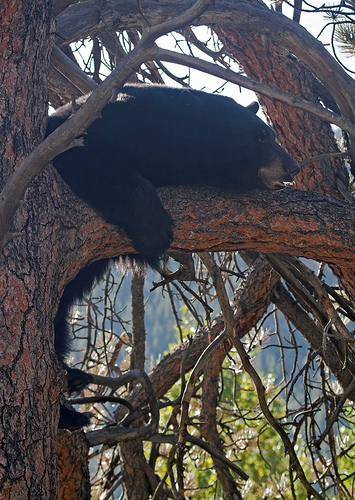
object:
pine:
[0, 0, 355, 500]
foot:
[64, 368, 93, 391]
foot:
[58, 404, 89, 432]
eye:
[258, 133, 266, 143]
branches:
[61, 250, 355, 500]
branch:
[0, 0, 354, 223]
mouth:
[261, 174, 293, 190]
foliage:
[227, 363, 259, 411]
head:
[199, 94, 302, 192]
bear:
[45, 83, 300, 430]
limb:
[54, 171, 355, 293]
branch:
[318, 1, 354, 75]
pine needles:
[321, 2, 355, 57]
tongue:
[275, 180, 285, 187]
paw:
[130, 203, 174, 258]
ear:
[246, 101, 259, 115]